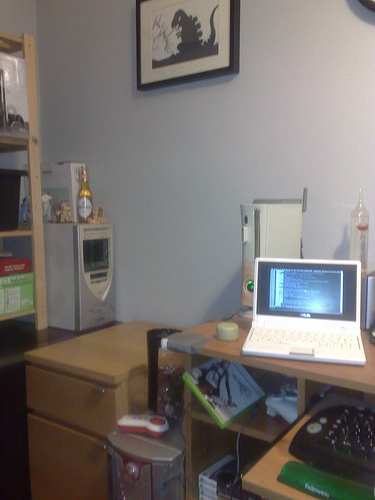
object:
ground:
[294, 98, 332, 144]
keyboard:
[287, 405, 373, 454]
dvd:
[182, 356, 265, 429]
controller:
[266, 381, 306, 424]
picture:
[136, 1, 241, 92]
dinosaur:
[170, 3, 219, 52]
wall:
[38, 1, 374, 327]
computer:
[46, 222, 114, 333]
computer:
[241, 256, 366, 368]